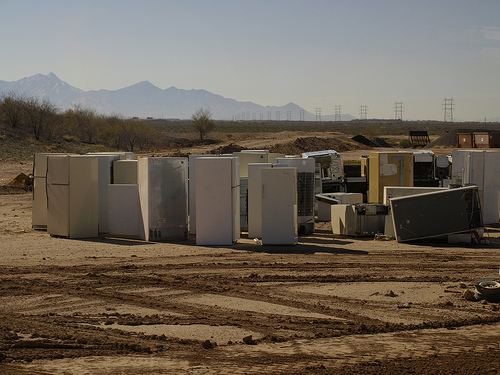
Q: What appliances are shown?
A: Refrigerators.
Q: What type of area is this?
A: A junkyard.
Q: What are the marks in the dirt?
A: Tire tracks.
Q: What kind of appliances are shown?
A: Refrigerators.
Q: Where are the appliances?
A: In a field.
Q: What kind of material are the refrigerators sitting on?
A: Sand.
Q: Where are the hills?
A: Far in the photo's background.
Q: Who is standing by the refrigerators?
A: No one is in the photo?.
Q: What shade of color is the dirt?
A: Brown.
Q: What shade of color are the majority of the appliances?
A: White.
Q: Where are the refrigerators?
A: In the dirt.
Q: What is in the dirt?
A: The refrigerators.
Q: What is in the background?
A: The mountains.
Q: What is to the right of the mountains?
A: Power lines.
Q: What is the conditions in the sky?
A: Clear but hazy.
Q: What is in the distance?
A: Mountains.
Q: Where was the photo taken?
A: Landfill.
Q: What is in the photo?
A: Refrigerators.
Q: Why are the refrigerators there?
A: Non-working.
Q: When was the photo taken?
A: Afternoon.